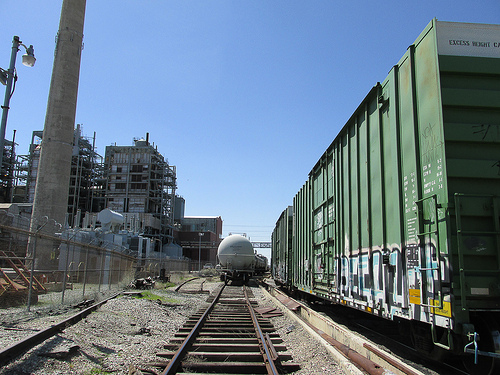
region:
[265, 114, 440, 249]
the train is green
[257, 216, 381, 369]
the train is green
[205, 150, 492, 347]
the train is green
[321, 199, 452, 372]
the train is green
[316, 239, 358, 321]
the train is green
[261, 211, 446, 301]
Graffiti on the side of a train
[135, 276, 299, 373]
Railroad tracks on gravel road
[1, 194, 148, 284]
Barbed wire fence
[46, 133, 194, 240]
Building under construction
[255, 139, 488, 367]
Green train cars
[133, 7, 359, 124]
Blue sky with no clouds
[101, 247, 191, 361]
Gravel next to railroad tracks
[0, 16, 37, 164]
Tall streetlight pole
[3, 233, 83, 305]
Equipment in a work yard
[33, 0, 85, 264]
Concrete pillar in a work yard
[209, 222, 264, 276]
rounded train cart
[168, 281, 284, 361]
train tracks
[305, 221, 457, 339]
graffiti on side of train cart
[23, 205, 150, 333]
barbed wire chain link fence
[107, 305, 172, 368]
gravel under and around tracks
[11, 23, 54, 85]
street light on pole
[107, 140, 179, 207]
building with multiple stories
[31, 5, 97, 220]
large concrete pole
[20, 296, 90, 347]
pipes along train tracks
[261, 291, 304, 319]
building supplies for tracks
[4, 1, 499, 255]
a sky with no clouds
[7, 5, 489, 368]
a scene outside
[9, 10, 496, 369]
a scene during the day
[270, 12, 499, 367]
a green train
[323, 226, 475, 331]
graffiti art on side of train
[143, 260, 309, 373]
train track in center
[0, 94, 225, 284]
a rundown looking group of buildings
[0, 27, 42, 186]
a lamp post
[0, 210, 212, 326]
a barbed wire fence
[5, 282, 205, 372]
a patch of gravel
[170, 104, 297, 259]
the sky is clear and visible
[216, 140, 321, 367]
the sky is clear and visible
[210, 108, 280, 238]
the sky is clear and visible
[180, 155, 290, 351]
the sky is clear and visible